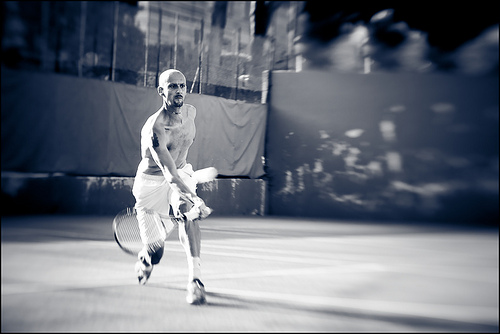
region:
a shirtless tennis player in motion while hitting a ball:
[105, 62, 217, 308]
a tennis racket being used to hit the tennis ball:
[113, 208, 215, 252]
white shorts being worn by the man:
[137, 173, 178, 214]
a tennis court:
[237, 245, 460, 327]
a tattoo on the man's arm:
[144, 130, 161, 154]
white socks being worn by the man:
[187, 251, 206, 277]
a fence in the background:
[70, 5, 268, 62]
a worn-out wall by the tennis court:
[298, 95, 498, 197]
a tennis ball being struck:
[197, 164, 220, 185]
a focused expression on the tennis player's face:
[151, 66, 201, 133]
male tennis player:
[127, 66, 217, 312]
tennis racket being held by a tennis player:
[108, 202, 210, 257]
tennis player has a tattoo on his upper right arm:
[149, 128, 163, 150]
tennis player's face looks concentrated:
[157, 65, 192, 112]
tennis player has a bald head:
[155, 67, 187, 110]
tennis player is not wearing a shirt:
[126, 63, 216, 306]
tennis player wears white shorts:
[130, 161, 200, 248]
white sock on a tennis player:
[186, 251, 202, 282]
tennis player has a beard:
[170, 92, 187, 108]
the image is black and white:
[0, 0, 498, 331]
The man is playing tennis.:
[90, 40, 246, 310]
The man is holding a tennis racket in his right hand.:
[80, 47, 236, 322]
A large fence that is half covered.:
[0, 10, 276, 170]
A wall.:
[270, 65, 495, 225]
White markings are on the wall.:
[275, 85, 490, 220]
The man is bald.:
[150, 60, 195, 115]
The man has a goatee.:
[150, 55, 190, 115]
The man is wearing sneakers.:
[110, 225, 230, 310]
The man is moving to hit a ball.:
[100, 55, 230, 300]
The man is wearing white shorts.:
[110, 60, 220, 320]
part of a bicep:
[152, 138, 174, 166]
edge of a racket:
[105, 208, 123, 248]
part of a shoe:
[174, 277, 211, 307]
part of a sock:
[182, 250, 203, 277]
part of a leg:
[179, 230, 205, 255]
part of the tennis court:
[316, 261, 360, 298]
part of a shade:
[343, 309, 379, 327]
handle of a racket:
[179, 205, 201, 220]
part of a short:
[141, 179, 176, 207]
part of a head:
[159, 64, 186, 79]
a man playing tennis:
[111, 69, 216, 306]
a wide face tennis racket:
[110, 210, 188, 255]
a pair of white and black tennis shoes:
[187, 278, 205, 304]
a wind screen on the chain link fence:
[1, 76, 263, 183]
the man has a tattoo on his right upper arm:
[149, 133, 160, 150]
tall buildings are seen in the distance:
[136, 1, 302, 92]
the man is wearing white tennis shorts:
[132, 164, 196, 244]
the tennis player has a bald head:
[156, 68, 187, 87]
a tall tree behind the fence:
[264, 2, 299, 73]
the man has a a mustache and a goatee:
[171, 94, 184, 107]